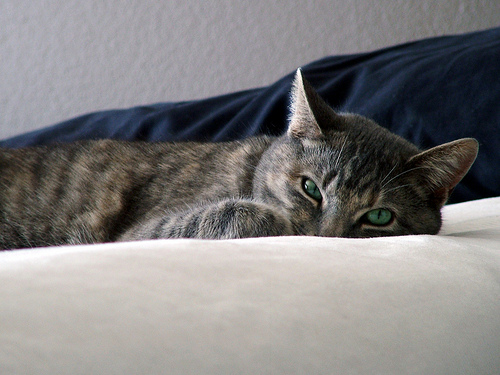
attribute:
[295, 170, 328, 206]
eye — green, white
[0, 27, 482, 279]
cat — laying, grey, gray, lying, bed, black, resting, waiting, looking, purring, enjoying, wanting, lying down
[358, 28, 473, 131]
cover — blue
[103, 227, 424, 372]
blanket — white, blue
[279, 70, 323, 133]
ear — grey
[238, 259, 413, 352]
cover — white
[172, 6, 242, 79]
wall — white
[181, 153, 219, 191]
fur — brown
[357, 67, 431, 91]
pillow — blue